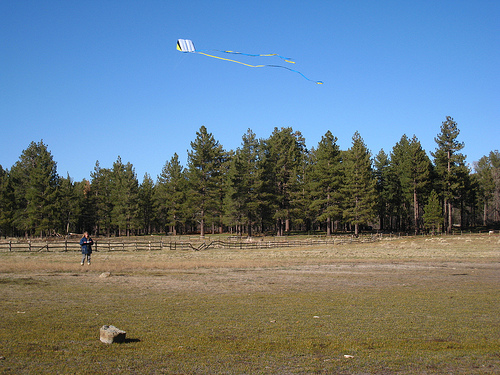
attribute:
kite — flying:
[176, 39, 323, 88]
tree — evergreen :
[12, 116, 497, 246]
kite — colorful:
[174, 38, 196, 55]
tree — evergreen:
[176, 180, 385, 202]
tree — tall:
[425, 111, 471, 238]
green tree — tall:
[6, 137, 58, 237]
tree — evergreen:
[79, 157, 130, 242]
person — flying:
[32, 189, 147, 303]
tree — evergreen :
[0, 133, 54, 235]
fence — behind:
[27, 230, 365, 245]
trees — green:
[1, 118, 499, 232]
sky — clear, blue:
[1, 1, 496, 184]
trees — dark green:
[231, 111, 458, 246]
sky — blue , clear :
[346, 5, 498, 117]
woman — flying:
[69, 227, 100, 272]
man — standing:
[76, 222, 116, 280]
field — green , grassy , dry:
[0, 232, 499, 373]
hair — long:
[79, 229, 89, 239]